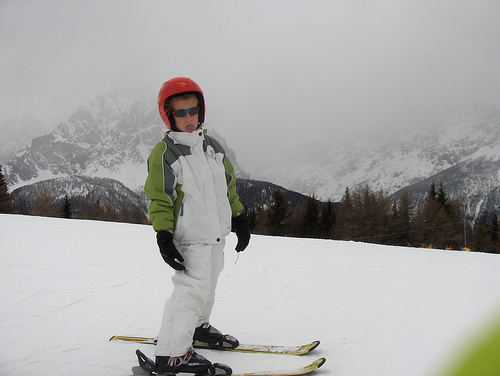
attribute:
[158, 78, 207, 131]
helmet — red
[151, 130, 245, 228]
jacket — white, green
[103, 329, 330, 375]
skis — yellou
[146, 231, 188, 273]
gloves — black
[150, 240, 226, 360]
pants — white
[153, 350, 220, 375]
ski shoes — black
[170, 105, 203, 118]
glasses — dark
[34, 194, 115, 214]
trees — dead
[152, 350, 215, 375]
ski boot — black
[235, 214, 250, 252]
glove — black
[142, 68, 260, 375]
kid — skiing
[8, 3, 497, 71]
sky — foggy